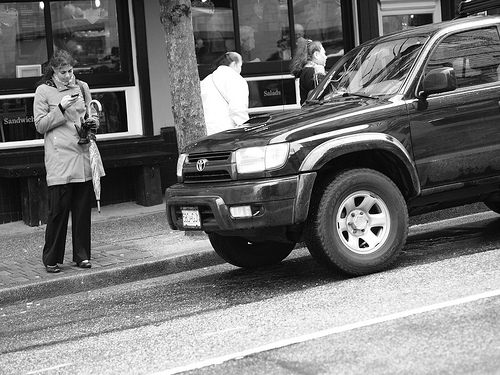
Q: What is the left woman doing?
A: Texting.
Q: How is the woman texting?
A: ON a phone.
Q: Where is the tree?
A: Behind the car.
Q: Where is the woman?
A: On the sidewalk.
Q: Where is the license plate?
A: On the vehicle.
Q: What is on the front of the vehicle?
A: A license plate.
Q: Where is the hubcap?
A: On the tire.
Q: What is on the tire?
A: The hubcap.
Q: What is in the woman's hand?
A: An umbrella.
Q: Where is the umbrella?
A: In the woman's hand.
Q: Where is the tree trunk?
A: On the sidewalk.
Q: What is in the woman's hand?
A: A phone.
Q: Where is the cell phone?
A: In the woman's hand.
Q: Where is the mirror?
A: On the vehicle.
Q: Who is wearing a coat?
A: A woman.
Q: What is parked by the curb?
A: A dark vehicle.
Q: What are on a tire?
A: Silver rims.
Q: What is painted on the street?
A: A line.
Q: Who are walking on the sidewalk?
A: Some People.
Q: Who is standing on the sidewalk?
A: A Woman.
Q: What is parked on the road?
A: A Car.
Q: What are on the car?
A: Wheels.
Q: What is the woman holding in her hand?
A: A cellphone.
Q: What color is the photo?
A: Black and white.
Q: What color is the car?
A: Black.